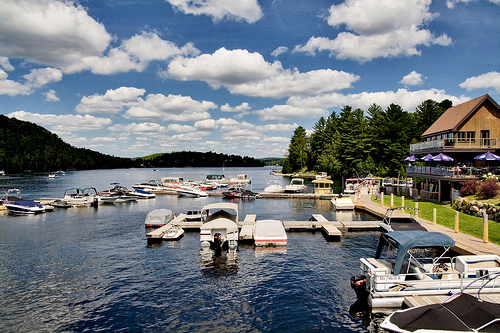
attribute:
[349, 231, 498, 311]
boat — blue, white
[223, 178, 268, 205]
boat — red, black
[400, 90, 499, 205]
house — brown, wooden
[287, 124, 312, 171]
tree — green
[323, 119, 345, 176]
tree — green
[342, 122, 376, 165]
tree — green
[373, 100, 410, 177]
tree — green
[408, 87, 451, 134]
tree — green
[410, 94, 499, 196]
house — brown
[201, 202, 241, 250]
boat — blue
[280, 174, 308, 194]
boat — blue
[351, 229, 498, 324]
boat — blue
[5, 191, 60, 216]
boat — blue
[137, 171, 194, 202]
boat — blue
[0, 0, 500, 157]
clouds — white, puffy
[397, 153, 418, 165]
umbrella — purple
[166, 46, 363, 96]
cloud — white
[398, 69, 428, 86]
cloud — white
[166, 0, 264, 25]
cloud — white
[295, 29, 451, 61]
cloud — white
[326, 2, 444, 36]
cloud — white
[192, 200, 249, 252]
boat — white 